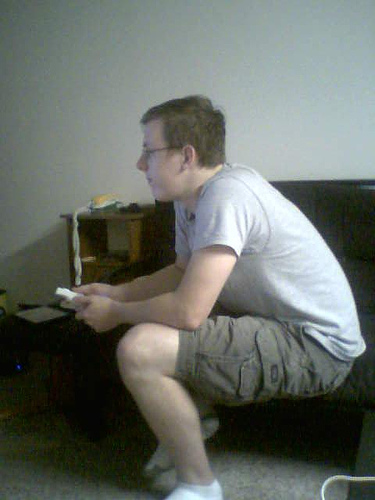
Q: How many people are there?
A: One.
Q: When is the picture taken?
A: Daytime.